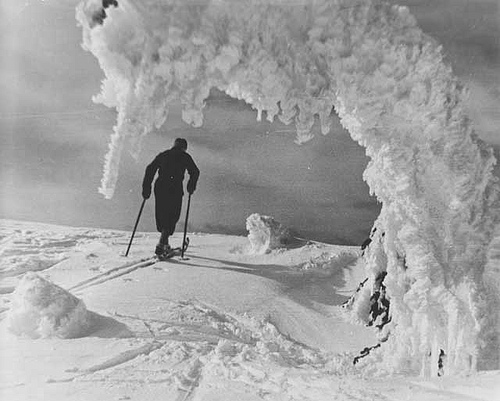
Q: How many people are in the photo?
A: One.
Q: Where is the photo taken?
A: Mountain.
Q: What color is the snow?
A: White.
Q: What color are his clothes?
A: Black.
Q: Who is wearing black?
A: The skier.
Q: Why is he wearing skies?
A: To ski.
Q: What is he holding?
A: Ski sticks.